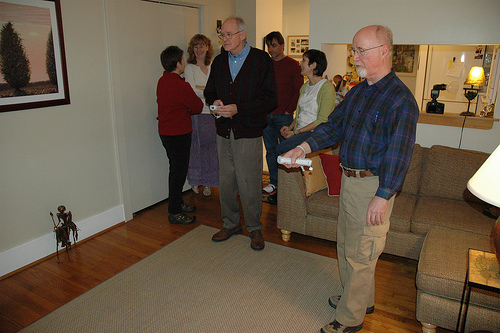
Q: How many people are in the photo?
A: 6.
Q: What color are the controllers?
A: White.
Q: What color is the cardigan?
A: Black.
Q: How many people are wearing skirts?
A: 1.